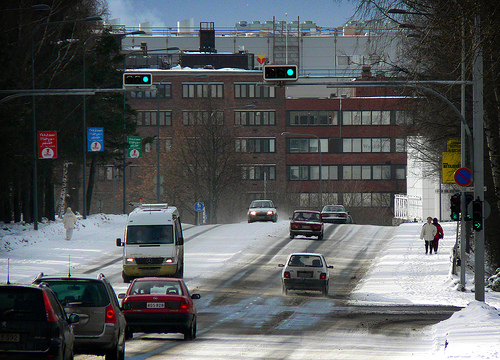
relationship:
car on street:
[276, 248, 347, 290] [1, 204, 398, 353]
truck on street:
[117, 204, 184, 283] [15, 210, 379, 353]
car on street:
[276, 248, 347, 290] [43, 209, 457, 359]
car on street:
[276, 248, 347, 290] [63, 196, 459, 358]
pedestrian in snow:
[56, 204, 87, 242] [5, 211, 497, 359]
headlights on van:
[122, 253, 175, 267] [118, 189, 201, 285]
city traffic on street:
[4, 176, 357, 342] [5, 200, 479, 356]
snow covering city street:
[2, 193, 497, 358] [30, 179, 463, 346]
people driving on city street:
[420, 217, 437, 255] [0, 223, 499, 360]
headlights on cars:
[107, 211, 277, 271] [10, 185, 358, 358]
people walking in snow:
[417, 209, 445, 257] [7, 205, 497, 345]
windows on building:
[179, 81, 224, 98] [67, 64, 472, 231]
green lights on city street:
[136, 63, 306, 87] [0, 223, 499, 360]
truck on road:
[117, 204, 184, 283] [55, 212, 378, 359]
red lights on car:
[282, 270, 327, 279] [272, 244, 333, 296]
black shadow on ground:
[370, 265, 454, 281] [201, 295, 430, 340]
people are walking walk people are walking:
[411, 212, 447, 248] [411, 212, 447, 248]